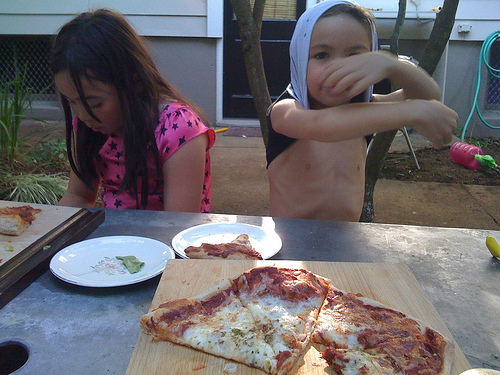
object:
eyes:
[86, 100, 106, 110]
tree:
[237, 0, 278, 150]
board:
[123, 258, 475, 374]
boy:
[258, 0, 465, 224]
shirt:
[287, 0, 380, 111]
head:
[285, 0, 383, 109]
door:
[219, 0, 315, 124]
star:
[111, 198, 123, 209]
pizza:
[181, 232, 264, 261]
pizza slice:
[137, 263, 333, 374]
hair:
[47, 6, 216, 209]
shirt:
[68, 92, 219, 215]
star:
[170, 122, 179, 131]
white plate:
[47, 234, 176, 291]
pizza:
[0, 202, 44, 239]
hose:
[457, 32, 500, 143]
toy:
[447, 139, 499, 172]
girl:
[48, 5, 219, 215]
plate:
[167, 219, 287, 261]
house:
[1, 0, 500, 142]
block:
[0, 198, 87, 271]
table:
[0, 206, 499, 374]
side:
[0, 0, 499, 141]